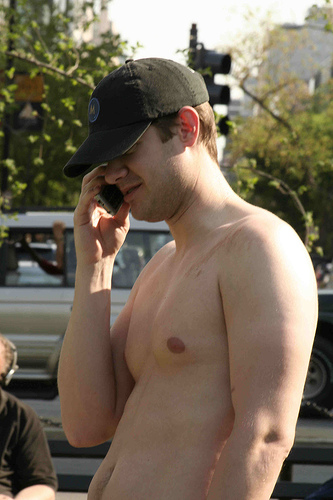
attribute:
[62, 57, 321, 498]
man — speaking, naked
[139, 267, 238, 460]
torso — bare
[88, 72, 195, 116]
cap — black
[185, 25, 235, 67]
traffic light — black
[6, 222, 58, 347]
car — silver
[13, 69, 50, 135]
sign — yellow